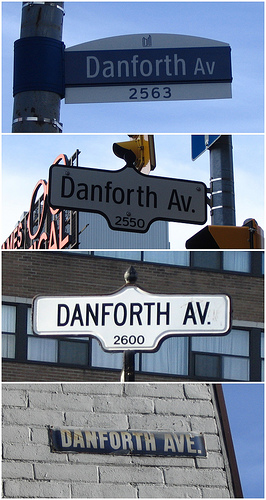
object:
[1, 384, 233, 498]
wall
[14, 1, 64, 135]
post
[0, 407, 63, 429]
brick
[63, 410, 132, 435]
brick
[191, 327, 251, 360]
window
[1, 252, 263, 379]
building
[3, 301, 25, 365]
window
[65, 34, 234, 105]
sign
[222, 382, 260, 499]
sky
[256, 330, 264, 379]
window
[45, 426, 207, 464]
sign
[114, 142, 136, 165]
light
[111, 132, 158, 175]
traffic light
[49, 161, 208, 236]
sign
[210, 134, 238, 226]
pole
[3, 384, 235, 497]
building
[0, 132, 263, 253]
sky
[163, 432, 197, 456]
writing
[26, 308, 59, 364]
window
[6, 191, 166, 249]
building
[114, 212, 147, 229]
number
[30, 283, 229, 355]
sign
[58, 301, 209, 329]
writing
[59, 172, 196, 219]
writing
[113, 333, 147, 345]
number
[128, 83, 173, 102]
number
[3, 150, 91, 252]
sign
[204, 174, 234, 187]
brace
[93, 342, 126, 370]
curtain